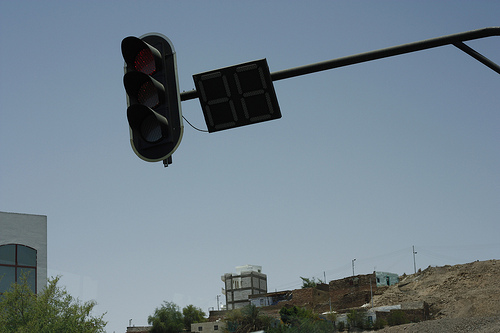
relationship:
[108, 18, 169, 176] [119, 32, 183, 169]
cones around light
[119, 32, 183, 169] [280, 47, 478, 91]
light on pole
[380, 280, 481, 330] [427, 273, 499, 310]
dirt on dirt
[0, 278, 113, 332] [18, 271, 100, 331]
leaves on tree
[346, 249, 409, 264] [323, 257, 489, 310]
power line on top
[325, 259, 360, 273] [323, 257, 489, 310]
power line on top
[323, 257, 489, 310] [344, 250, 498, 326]
top of incline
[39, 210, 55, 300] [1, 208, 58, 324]
corner of building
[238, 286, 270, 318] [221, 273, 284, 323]
part of a house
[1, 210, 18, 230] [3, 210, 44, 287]
side of a wall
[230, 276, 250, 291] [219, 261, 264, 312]
side of a wall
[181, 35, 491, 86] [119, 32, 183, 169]
pole with light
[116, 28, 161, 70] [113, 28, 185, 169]
traffic light on panel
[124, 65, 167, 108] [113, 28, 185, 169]
traffic light on panel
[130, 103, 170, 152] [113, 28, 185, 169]
traffic light on panel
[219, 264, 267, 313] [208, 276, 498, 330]
building on terrain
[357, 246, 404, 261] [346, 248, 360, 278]
utility line strung between pole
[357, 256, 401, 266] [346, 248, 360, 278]
utility line strung between pole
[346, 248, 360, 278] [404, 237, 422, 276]
pole strung between pole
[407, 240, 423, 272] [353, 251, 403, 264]
pole with utility line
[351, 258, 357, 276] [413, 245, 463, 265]
pole with utility line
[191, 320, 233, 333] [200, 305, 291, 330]
building at base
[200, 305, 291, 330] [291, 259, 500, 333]
base of base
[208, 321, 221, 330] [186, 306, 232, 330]
window in building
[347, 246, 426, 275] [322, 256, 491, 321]
poles on hill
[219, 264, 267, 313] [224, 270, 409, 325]
building on hill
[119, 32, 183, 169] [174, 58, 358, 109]
light on pole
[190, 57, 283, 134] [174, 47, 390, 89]
seconds on pole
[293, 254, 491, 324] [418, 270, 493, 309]
hill with dirt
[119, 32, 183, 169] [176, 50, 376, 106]
light on pole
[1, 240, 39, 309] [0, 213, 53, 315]
window on building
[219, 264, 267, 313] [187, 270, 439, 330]
building on hillside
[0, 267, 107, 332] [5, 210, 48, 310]
tree in front of building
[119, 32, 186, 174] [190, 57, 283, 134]
light near seconds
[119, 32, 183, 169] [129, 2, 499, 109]
light on a pole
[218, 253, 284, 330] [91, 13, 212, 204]
building by traffic light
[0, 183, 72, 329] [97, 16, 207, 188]
bilding by traffic light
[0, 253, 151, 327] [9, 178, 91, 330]
tree by building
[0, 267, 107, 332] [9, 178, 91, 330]
tree by building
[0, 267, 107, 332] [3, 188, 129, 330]
tree by building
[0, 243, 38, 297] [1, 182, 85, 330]
window on building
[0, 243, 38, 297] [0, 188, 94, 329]
window on building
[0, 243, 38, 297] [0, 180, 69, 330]
window on building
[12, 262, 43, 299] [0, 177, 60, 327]
window on building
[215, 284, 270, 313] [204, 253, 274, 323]
window on a building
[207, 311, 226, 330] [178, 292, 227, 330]
window on a building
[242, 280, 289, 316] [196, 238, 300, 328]
window on a building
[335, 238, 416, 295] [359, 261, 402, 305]
window on a building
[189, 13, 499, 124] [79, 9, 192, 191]
pole near traffic light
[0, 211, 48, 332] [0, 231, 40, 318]
bilding has a window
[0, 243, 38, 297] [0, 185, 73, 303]
window on wall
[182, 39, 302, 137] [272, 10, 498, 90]
seconds on pole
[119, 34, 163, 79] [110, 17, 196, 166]
light on traffic light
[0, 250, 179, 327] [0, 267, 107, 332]
leaves on tree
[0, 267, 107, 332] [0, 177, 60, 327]
tree in front of building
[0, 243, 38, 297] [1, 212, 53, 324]
window of a building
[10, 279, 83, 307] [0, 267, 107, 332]
top of tree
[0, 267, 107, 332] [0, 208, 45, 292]
tree near a building